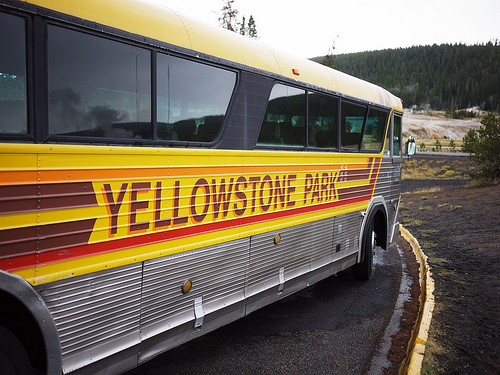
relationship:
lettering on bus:
[96, 167, 343, 234] [2, 38, 409, 371]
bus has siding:
[0, 0, 419, 372] [55, 222, 360, 358]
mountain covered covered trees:
[372, 113, 497, 158] [367, 42, 487, 69]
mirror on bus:
[400, 133, 421, 165] [81, 9, 407, 327]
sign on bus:
[95, 168, 342, 232] [0, 0, 414, 372]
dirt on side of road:
[396, 180, 498, 373] [125, 242, 417, 373]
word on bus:
[102, 169, 297, 236] [0, 0, 414, 372]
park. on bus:
[304, 172, 338, 204] [0, 0, 414, 372]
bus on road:
[0, 0, 414, 372] [124, 225, 427, 373]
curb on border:
[404, 246, 456, 371] [395, 218, 434, 374]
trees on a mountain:
[308, 39, 498, 115] [301, 45, 498, 113]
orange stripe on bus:
[3, 158, 371, 188] [140, 8, 420, 290]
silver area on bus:
[45, 230, 335, 352] [0, 0, 414, 372]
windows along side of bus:
[1, 0, 404, 152] [0, 0, 414, 372]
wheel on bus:
[358, 208, 379, 280] [0, 0, 414, 372]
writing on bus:
[94, 160, 352, 216] [0, 0, 414, 372]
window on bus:
[47, 16, 269, 166] [0, 0, 414, 372]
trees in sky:
[214, 0, 261, 39] [288, 10, 326, 41]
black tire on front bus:
[355, 224, 376, 276] [0, 0, 414, 372]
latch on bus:
[190, 288, 209, 338] [0, 0, 414, 372]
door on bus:
[138, 237, 251, 364] [0, 0, 414, 372]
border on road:
[395, 218, 434, 373] [124, 225, 427, 373]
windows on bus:
[25, 8, 391, 178] [18, 2, 451, 361]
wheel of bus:
[364, 208, 379, 273] [0, 0, 414, 372]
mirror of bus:
[402, 135, 417, 161] [0, 0, 414, 372]